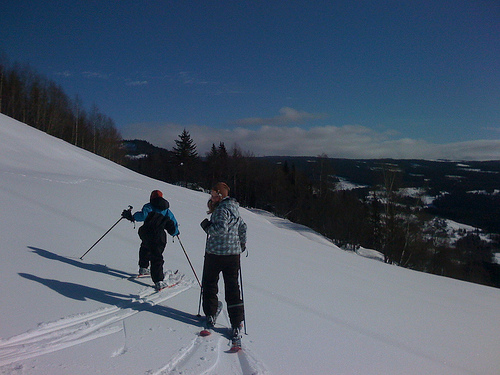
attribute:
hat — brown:
[204, 180, 234, 211]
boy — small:
[125, 185, 188, 301]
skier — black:
[126, 193, 186, 286]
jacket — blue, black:
[135, 201, 179, 247]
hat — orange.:
[150, 189, 163, 202]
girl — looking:
[199, 181, 249, 328]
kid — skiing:
[128, 190, 178, 291]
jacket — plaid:
[201, 196, 248, 260]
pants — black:
[133, 226, 170, 290]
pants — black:
[204, 257, 301, 332]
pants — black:
[194, 257, 258, 329]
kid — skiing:
[121, 188, 181, 290]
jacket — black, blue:
[129, 201, 180, 253]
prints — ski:
[151, 337, 261, 371]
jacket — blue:
[201, 198, 252, 260]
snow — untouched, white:
[3, 110, 484, 372]